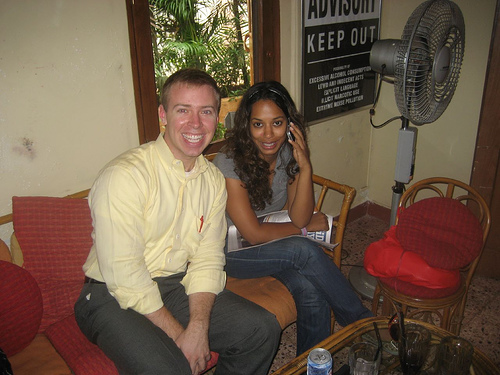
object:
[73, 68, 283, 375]
man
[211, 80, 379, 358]
woman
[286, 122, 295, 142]
cell phone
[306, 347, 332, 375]
can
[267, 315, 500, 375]
table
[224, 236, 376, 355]
pants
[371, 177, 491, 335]
chair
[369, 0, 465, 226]
fan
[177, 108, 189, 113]
eye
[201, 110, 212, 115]
eye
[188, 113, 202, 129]
nose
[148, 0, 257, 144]
window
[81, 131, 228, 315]
shirt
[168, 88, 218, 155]
face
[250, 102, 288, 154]
face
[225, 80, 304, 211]
hair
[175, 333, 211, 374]
hand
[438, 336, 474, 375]
bottle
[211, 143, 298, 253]
shirt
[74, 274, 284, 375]
pants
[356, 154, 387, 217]
corner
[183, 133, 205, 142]
teeth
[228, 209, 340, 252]
newspaper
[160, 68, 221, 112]
hair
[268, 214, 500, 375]
floor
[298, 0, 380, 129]
sign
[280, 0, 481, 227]
wall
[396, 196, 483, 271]
pillow